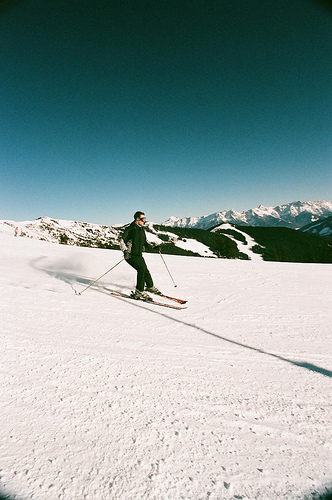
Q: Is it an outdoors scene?
A: Yes, it is outdoors.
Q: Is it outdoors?
A: Yes, it is outdoors.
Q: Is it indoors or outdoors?
A: It is outdoors.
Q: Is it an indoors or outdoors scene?
A: It is outdoors.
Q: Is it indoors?
A: No, it is outdoors.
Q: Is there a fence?
A: No, there are no fences.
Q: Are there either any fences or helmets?
A: No, there are no fences or helmets.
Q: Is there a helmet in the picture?
A: No, there are no helmets.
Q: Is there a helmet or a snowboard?
A: No, there are no helmets or snowboards.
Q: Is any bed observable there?
A: No, there are no beds.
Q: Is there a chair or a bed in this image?
A: No, there are no beds or chairs.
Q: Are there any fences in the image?
A: No, there are no fences.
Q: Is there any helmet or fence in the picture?
A: No, there are no fences or helmets.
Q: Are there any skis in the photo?
A: Yes, there are skis.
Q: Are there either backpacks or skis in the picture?
A: Yes, there are skis.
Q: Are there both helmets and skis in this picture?
A: No, there are skis but no helmets.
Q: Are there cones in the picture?
A: No, there are no cones.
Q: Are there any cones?
A: No, there are no cones.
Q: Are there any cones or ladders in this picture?
A: No, there are no cones or ladders.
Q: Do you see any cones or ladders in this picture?
A: No, there are no cones or ladders.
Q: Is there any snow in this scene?
A: Yes, there is snow.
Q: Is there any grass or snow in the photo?
A: Yes, there is snow.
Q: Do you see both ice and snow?
A: No, there is snow but no ice.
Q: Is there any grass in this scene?
A: No, there is no grass.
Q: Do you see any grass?
A: No, there is no grass.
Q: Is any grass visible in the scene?
A: No, there is no grass.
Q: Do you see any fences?
A: No, there are no fences.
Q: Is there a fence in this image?
A: No, there are no fences.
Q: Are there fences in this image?
A: No, there are no fences.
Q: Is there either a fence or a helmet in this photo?
A: No, there are no fences or helmets.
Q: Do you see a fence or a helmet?
A: No, there are no fences or helmets.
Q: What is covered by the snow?
A: The mountains are covered by the snow.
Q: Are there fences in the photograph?
A: No, there are no fences.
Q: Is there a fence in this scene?
A: No, there are no fences.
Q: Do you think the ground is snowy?
A: Yes, the ground is snowy.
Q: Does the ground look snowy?
A: Yes, the ground is snowy.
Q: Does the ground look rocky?
A: No, the ground is snowy.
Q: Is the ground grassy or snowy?
A: The ground is snowy.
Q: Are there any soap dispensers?
A: No, there are no soap dispensers.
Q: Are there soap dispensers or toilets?
A: No, there are no soap dispensers or toilets.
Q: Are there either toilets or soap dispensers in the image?
A: No, there are no soap dispensers or toilets.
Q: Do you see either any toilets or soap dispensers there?
A: No, there are no soap dispensers or toilets.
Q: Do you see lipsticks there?
A: No, there are no lipsticks.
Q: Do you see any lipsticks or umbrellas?
A: No, there are no lipsticks or umbrellas.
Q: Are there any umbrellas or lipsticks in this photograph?
A: No, there are no lipsticks or umbrellas.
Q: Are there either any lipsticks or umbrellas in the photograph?
A: No, there are no lipsticks or umbrellas.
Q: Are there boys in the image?
A: No, there are no boys.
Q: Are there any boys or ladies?
A: No, there are no boys or ladies.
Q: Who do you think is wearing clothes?
A: The man is wearing clothes.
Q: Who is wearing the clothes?
A: The man is wearing clothes.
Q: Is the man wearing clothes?
A: Yes, the man is wearing clothes.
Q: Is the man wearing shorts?
A: No, the man is wearing clothes.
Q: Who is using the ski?
A: The man is using the ski.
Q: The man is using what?
A: The man is using a ski.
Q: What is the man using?
A: The man is using a ski.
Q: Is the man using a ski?
A: Yes, the man is using a ski.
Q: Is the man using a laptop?
A: No, the man is using a ski.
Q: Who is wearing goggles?
A: The man is wearing goggles.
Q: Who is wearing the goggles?
A: The man is wearing goggles.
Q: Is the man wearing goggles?
A: Yes, the man is wearing goggles.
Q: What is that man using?
A: The man is using a ski.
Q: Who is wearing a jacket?
A: The man is wearing a jacket.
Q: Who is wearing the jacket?
A: The man is wearing a jacket.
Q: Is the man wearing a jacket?
A: Yes, the man is wearing a jacket.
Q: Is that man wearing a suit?
A: No, the man is wearing a jacket.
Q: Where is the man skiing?
A: The man is skiing on the hill.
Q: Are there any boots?
A: Yes, there are boots.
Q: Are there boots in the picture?
A: Yes, there are boots.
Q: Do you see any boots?
A: Yes, there are boots.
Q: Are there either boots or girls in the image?
A: Yes, there are boots.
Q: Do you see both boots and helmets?
A: No, there are boots but no helmets.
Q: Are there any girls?
A: No, there are no girls.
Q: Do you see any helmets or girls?
A: No, there are no girls or helmets.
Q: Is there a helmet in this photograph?
A: No, there are no helmets.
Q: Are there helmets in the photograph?
A: No, there are no helmets.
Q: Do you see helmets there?
A: No, there are no helmets.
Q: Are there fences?
A: No, there are no fences.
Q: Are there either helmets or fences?
A: No, there are no fences or helmets.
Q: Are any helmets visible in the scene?
A: No, there are no helmets.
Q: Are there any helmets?
A: No, there are no helmets.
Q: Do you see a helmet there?
A: No, there are no helmets.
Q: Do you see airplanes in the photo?
A: No, there are no airplanes.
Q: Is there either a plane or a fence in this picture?
A: No, there are no airplanes or fences.